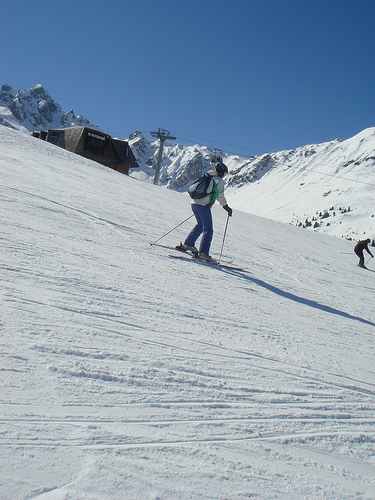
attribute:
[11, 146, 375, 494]
snow — white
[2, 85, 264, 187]
mountains — snow-covered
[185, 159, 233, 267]
skier — leaning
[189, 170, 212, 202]
backpack — white, black, blue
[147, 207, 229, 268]
poles — silver, long, black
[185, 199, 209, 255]
pants — purple, blue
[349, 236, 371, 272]
skier — shadowed, in distance, in black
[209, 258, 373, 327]
shadow — thin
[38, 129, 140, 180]
building — brown, wooded, angular, ski lodge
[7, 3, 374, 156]
sky — above, clear, blue, bright, cloudless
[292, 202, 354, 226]
pines — grouped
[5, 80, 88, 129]
rocks — jagged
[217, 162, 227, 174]
cap — blue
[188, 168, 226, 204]
jacket — white